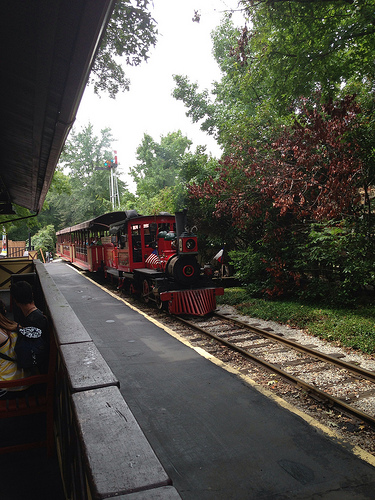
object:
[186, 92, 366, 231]
leaves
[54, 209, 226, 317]
train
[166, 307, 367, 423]
tracks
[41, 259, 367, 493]
pavement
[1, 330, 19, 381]
shirt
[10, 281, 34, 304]
hair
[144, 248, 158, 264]
flag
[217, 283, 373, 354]
grass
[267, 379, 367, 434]
leaves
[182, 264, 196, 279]
circle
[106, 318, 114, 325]
spot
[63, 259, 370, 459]
line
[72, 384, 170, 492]
stone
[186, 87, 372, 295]
tree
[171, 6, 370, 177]
tree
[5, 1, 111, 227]
hang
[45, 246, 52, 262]
person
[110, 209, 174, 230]
roof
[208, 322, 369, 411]
gravel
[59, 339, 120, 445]
block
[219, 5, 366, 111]
leaves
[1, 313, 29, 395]
person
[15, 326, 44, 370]
backpack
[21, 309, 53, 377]
shirt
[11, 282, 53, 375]
person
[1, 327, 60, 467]
bench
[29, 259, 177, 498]
wall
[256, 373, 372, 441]
gravel